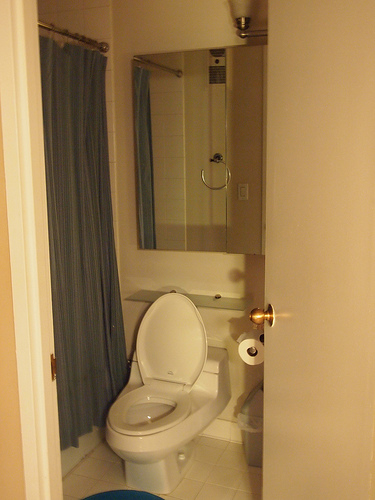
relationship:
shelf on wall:
[124, 289, 252, 314] [111, 2, 265, 431]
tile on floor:
[62, 438, 264, 500] [59, 423, 264, 499]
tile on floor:
[62, 438, 264, 500] [64, 429, 260, 498]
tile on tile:
[62, 438, 264, 500] [62, 438, 264, 500]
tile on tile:
[211, 447, 250, 471] [62, 438, 264, 500]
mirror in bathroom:
[134, 40, 266, 248] [1, 0, 373, 497]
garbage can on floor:
[238, 378, 264, 469] [64, 429, 260, 498]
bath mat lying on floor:
[83, 487, 164, 498] [62, 411, 319, 498]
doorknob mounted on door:
[249, 303, 276, 328] [267, 2, 360, 497]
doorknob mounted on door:
[243, 302, 277, 328] [269, 1, 351, 498]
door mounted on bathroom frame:
[249, 4, 371, 498] [3, 1, 62, 498]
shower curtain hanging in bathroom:
[39, 34, 130, 453] [9, 5, 266, 491]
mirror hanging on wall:
[134, 40, 266, 254] [111, 2, 265, 431]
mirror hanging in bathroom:
[134, 40, 266, 254] [35, 4, 268, 498]